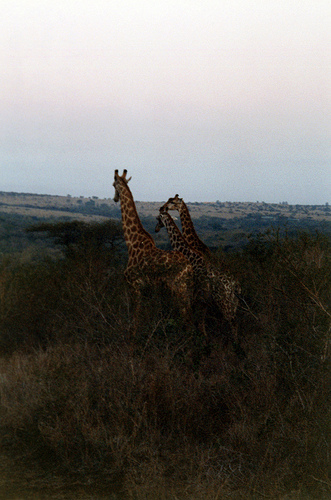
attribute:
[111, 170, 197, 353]
giraffe — brown, wild, spotted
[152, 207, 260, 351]
giraffe — spotted, short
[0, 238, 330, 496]
grass — green in color, brown in color, green, dry, brown colored, brown, green colored, wiry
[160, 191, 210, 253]
giraffe — standing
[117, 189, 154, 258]
neck — tall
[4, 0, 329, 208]
sky — grey, white in color, clear, light blue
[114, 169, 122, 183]
horn — brown'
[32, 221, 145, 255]
tree — green, green colored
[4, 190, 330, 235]
field — brown